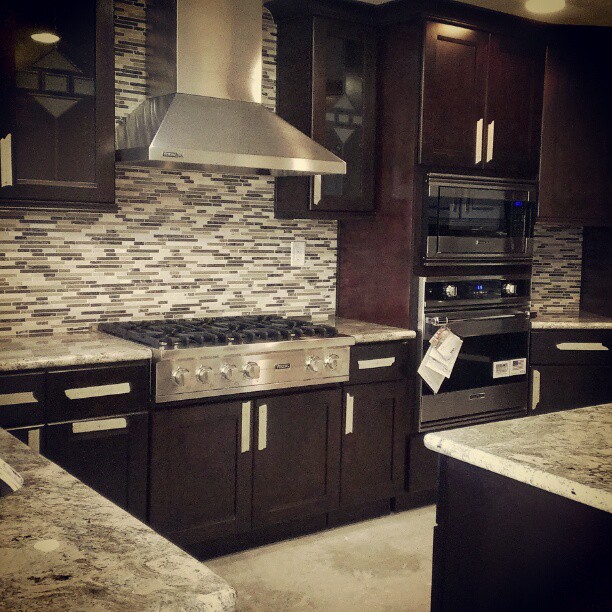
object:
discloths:
[407, 321, 462, 398]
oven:
[419, 326, 535, 430]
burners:
[102, 284, 349, 342]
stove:
[176, 333, 279, 424]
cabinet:
[213, 386, 290, 493]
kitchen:
[133, 288, 366, 545]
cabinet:
[454, 123, 487, 155]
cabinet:
[501, 151, 521, 164]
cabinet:
[545, 388, 559, 412]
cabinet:
[572, 140, 576, 163]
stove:
[157, 367, 346, 471]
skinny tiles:
[128, 253, 225, 308]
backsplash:
[88, 209, 260, 351]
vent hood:
[134, 62, 278, 132]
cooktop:
[141, 302, 335, 353]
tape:
[8, 371, 133, 452]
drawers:
[30, 375, 149, 499]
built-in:
[415, 181, 528, 245]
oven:
[507, 188, 554, 226]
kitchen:
[0, 149, 604, 567]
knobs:
[151, 345, 280, 408]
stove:
[168, 286, 361, 511]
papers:
[407, 316, 470, 387]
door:
[429, 306, 496, 350]